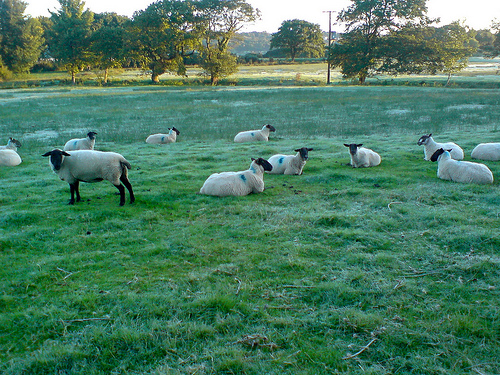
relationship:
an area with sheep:
[4, 87, 496, 373] [42, 149, 135, 206]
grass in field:
[2, 87, 496, 374] [0, 49, 493, 373]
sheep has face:
[42, 149, 135, 206] [42, 149, 70, 171]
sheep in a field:
[42, 149, 135, 206] [0, 49, 493, 373]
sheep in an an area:
[42, 149, 135, 206] [4, 87, 496, 373]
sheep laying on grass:
[0, 121, 483, 206] [2, 87, 496, 374]